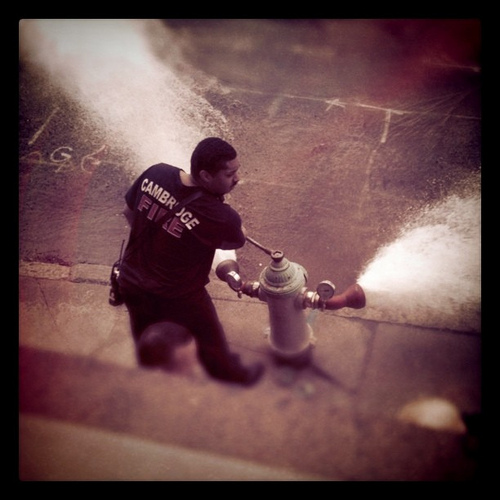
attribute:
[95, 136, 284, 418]
man — walking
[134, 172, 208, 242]
letters — white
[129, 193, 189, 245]
letters — red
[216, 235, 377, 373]
fire hydrant — red, white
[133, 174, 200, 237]
cambridge fire — word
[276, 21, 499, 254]
street — black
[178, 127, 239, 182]
short hair — curly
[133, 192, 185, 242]
fire — word